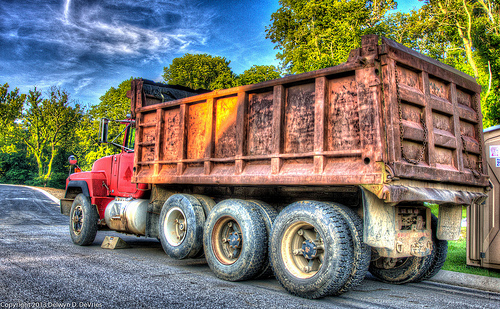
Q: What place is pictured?
A: It is a road.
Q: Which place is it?
A: It is a road.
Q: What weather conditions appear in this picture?
A: It is cloudy.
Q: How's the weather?
A: It is cloudy.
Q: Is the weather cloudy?
A: Yes, it is cloudy.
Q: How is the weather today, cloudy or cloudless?
A: It is cloudy.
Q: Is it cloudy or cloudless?
A: It is cloudy.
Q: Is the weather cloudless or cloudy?
A: It is cloudy.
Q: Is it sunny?
A: No, it is cloudy.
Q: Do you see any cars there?
A: No, there are no cars.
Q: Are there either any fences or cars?
A: No, there are no cars or fences.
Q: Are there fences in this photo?
A: No, there are no fences.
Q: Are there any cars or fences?
A: No, there are no fences or cars.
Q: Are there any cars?
A: No, there are no cars.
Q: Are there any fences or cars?
A: No, there are no cars or fences.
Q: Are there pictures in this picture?
A: No, there are no pictures.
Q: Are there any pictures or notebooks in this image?
A: No, there are no pictures or notebooks.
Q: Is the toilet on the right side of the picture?
A: Yes, the toilet is on the right of the image.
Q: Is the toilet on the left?
A: No, the toilet is on the right of the image.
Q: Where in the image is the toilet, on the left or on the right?
A: The toilet is on the right of the image.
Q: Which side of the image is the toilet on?
A: The toilet is on the right of the image.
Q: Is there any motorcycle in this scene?
A: No, there are no motorcycles.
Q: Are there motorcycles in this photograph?
A: No, there are no motorcycles.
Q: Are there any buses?
A: No, there are no buses.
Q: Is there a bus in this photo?
A: No, there are no buses.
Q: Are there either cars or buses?
A: No, there are no buses or cars.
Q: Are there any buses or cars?
A: No, there are no buses or cars.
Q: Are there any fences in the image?
A: No, there are no fences.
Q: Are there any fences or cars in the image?
A: No, there are no fences or cars.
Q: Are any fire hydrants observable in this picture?
A: No, there are no fire hydrants.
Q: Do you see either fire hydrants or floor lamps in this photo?
A: No, there are no fire hydrants or floor lamps.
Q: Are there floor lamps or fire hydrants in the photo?
A: No, there are no fire hydrants or floor lamps.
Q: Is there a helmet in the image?
A: No, there are no helmets.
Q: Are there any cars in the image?
A: No, there are no cars.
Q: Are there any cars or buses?
A: No, there are no cars or buses.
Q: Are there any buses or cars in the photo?
A: No, there are no cars or buses.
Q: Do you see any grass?
A: Yes, there is grass.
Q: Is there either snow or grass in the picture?
A: Yes, there is grass.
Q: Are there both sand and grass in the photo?
A: No, there is grass but no sand.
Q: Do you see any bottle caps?
A: No, there are no bottle caps.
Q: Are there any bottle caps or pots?
A: No, there are no bottle caps or pots.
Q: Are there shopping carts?
A: No, there are no shopping carts.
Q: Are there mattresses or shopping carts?
A: No, there are no shopping carts or mattresses.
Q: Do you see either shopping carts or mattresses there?
A: No, there are no shopping carts or mattresses.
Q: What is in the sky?
A: The clouds are in the sky.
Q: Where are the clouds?
A: The clouds are in the sky.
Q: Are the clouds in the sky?
A: Yes, the clouds are in the sky.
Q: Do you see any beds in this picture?
A: Yes, there is a bed.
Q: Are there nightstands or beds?
A: Yes, there is a bed.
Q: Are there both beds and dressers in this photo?
A: No, there is a bed but no dressers.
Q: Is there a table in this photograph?
A: No, there are no tables.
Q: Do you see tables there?
A: No, there are no tables.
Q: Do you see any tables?
A: No, there are no tables.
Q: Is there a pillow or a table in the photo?
A: No, there are no tables or pillows.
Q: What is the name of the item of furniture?
A: The piece of furniture is a bed.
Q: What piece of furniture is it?
A: The piece of furniture is a bed.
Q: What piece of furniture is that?
A: This is a bed.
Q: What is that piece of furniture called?
A: This is a bed.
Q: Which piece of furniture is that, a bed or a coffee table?
A: This is a bed.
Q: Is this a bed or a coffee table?
A: This is a bed.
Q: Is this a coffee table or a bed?
A: This is a bed.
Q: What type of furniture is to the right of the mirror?
A: The piece of furniture is a bed.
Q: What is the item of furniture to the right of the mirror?
A: The piece of furniture is a bed.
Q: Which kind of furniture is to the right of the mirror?
A: The piece of furniture is a bed.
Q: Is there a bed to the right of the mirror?
A: Yes, there is a bed to the right of the mirror.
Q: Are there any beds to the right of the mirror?
A: Yes, there is a bed to the right of the mirror.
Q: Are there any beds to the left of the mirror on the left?
A: No, the bed is to the right of the mirror.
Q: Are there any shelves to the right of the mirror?
A: No, there is a bed to the right of the mirror.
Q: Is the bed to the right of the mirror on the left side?
A: Yes, the bed is to the right of the mirror.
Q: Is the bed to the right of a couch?
A: No, the bed is to the right of the mirror.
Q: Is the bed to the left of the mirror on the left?
A: No, the bed is to the right of the mirror.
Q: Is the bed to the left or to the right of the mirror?
A: The bed is to the right of the mirror.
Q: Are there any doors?
A: Yes, there is a door.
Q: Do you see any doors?
A: Yes, there is a door.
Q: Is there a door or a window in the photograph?
A: Yes, there is a door.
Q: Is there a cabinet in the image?
A: No, there are no cabinets.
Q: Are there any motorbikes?
A: No, there are no motorbikes.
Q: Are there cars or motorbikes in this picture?
A: No, there are no motorbikes or cars.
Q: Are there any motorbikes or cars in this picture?
A: No, there are no motorbikes or cars.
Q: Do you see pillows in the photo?
A: No, there are no pillows.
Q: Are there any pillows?
A: No, there are no pillows.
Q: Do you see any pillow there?
A: No, there are no pillows.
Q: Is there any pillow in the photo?
A: No, there are no pillows.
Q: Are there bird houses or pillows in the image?
A: No, there are no pillows or bird houses.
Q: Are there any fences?
A: No, there are no fences.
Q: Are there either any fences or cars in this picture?
A: No, there are no fences or cars.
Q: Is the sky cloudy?
A: Yes, the sky is cloudy.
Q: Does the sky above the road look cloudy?
A: Yes, the sky is cloudy.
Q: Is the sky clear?
A: No, the sky is cloudy.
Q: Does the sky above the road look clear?
A: No, the sky is cloudy.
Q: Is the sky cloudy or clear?
A: The sky is cloudy.